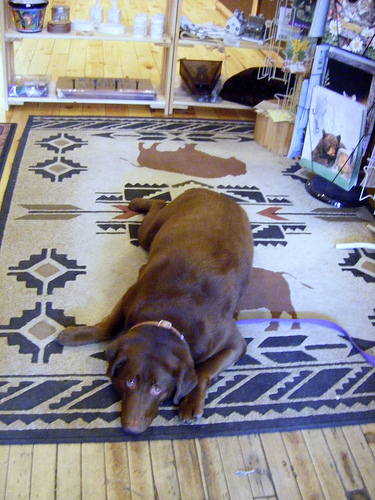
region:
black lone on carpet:
[287, 367, 351, 397]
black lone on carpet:
[203, 374, 244, 401]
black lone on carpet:
[50, 377, 104, 412]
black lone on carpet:
[7, 377, 77, 418]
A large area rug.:
[3, 112, 370, 430]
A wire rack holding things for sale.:
[255, 3, 311, 110]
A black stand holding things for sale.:
[297, 2, 374, 197]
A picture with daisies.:
[328, 0, 374, 56]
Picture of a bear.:
[294, 92, 354, 176]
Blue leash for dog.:
[59, 297, 374, 436]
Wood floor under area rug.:
[9, 108, 372, 493]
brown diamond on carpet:
[36, 261, 55, 278]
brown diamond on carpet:
[28, 318, 56, 339]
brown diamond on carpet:
[49, 163, 66, 174]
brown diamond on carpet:
[52, 138, 69, 146]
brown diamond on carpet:
[361, 259, 372, 275]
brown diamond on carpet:
[299, 170, 313, 179]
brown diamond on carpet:
[45, 52, 68, 75]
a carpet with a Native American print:
[0, 110, 373, 446]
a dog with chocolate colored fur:
[40, 166, 292, 449]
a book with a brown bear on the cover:
[289, 75, 374, 211]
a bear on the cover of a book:
[297, 119, 365, 185]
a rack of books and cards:
[252, 0, 374, 213]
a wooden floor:
[0, 415, 372, 499]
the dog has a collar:
[44, 193, 303, 441]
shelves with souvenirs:
[3, 2, 330, 142]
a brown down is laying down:
[66, 188, 252, 432]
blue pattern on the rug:
[3, 362, 367, 435]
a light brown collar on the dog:
[127, 320, 193, 349]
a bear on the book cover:
[309, 130, 347, 164]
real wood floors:
[12, 425, 374, 498]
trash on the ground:
[233, 468, 255, 475]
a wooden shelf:
[5, 0, 275, 116]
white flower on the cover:
[324, 0, 373, 58]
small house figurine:
[224, 9, 246, 36]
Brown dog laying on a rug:
[57, 186, 253, 437]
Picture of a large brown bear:
[311, 129, 347, 171]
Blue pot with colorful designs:
[9, 1, 50, 33]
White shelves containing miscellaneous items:
[1, 0, 310, 110]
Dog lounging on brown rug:
[57, 186, 253, 435]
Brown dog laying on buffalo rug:
[3, 114, 373, 445]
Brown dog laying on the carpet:
[64, 173, 280, 438]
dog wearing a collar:
[126, 317, 193, 353]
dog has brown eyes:
[120, 376, 165, 400]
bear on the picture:
[312, 130, 345, 171]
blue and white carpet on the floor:
[10, 110, 371, 442]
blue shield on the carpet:
[19, 126, 93, 197]